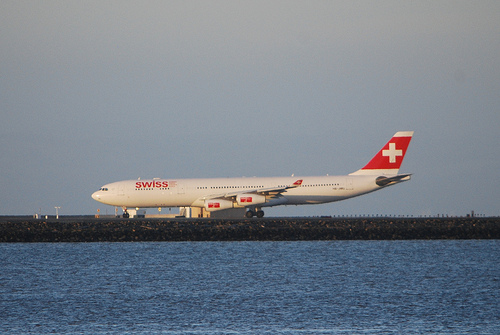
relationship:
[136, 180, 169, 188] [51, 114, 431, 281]
letter on plane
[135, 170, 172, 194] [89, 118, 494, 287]
letter on plane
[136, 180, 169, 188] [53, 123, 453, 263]
letter on plane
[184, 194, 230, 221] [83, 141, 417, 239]
decal on plane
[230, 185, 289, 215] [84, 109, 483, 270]
decal on plane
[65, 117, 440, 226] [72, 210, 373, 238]
airliner on tarmac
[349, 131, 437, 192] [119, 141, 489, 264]
tail on plane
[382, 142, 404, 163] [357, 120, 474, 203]
cross on tail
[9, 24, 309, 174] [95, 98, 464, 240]
sky above plane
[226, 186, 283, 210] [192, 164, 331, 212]
engine under wing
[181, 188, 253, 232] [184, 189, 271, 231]
engine under wing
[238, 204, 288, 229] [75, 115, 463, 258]
gear under plane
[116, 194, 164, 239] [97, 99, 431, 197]
gear under plane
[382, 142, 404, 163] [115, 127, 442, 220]
cross on plane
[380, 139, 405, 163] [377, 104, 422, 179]
cross on background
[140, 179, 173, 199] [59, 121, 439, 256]
swiss on plane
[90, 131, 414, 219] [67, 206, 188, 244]
airliner on runway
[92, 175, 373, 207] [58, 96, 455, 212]
part on plane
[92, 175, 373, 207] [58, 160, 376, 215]
part on plane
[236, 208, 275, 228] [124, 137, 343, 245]
part on plane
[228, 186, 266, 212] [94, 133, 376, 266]
part on plane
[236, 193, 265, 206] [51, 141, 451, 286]
part on plane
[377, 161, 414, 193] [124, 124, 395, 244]
part on plane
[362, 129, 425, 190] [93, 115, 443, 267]
part on plane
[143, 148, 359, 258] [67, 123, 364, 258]
part on plane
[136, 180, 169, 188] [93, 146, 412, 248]
letter on plane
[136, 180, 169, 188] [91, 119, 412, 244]
letter on plane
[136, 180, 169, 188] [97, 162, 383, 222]
letter on plane